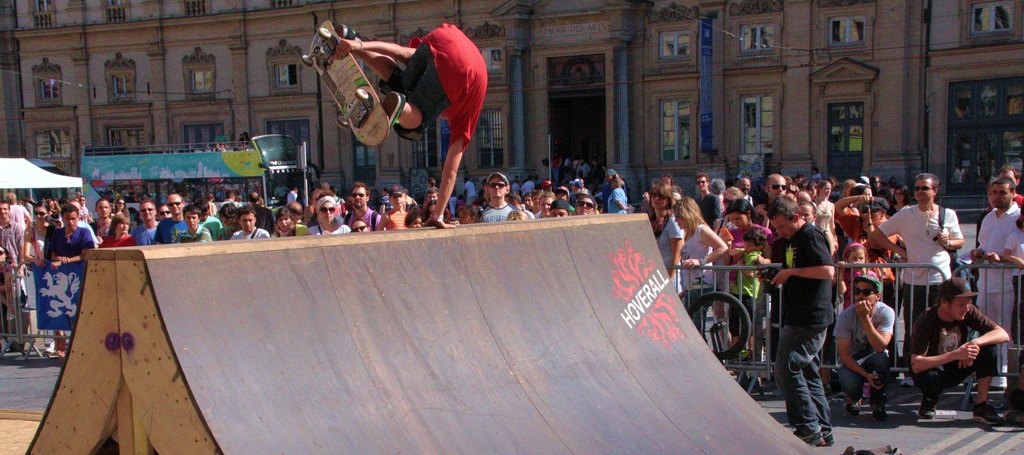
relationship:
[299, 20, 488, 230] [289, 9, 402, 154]
person with skateboard